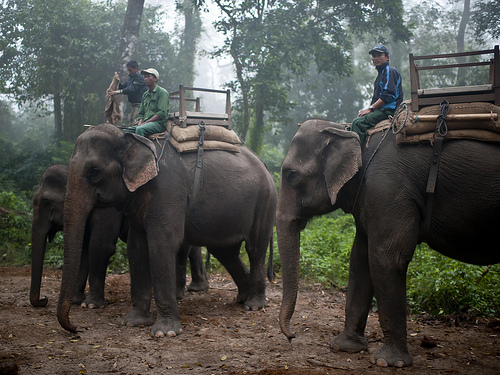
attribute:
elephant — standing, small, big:
[61, 130, 281, 316]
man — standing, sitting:
[116, 63, 144, 108]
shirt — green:
[132, 85, 179, 119]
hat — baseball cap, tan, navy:
[139, 67, 158, 79]